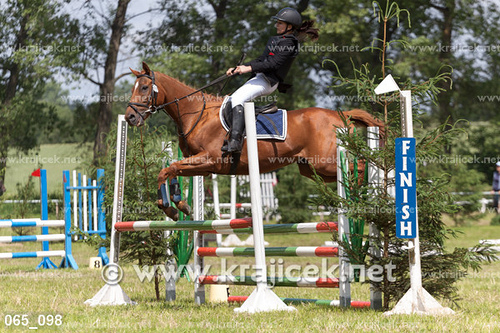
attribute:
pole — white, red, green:
[195, 244, 340, 256]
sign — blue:
[392, 136, 419, 239]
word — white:
[399, 136, 414, 236]